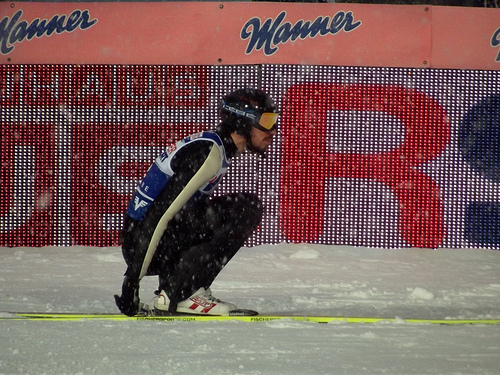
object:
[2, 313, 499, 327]
skis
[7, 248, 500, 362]
snow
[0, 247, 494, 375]
ground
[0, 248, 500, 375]
ice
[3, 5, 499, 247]
sign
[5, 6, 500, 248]
background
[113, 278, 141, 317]
gloves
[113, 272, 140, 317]
hands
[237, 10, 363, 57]
manner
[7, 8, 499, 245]
wall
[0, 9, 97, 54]
logos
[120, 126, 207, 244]
back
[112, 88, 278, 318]
man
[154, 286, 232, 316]
shoes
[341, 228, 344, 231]
led lights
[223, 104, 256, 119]
strap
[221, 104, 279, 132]
goggles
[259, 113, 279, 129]
tint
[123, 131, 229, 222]
vest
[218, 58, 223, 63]
rivets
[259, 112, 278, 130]
lens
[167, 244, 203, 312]
binder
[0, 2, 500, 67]
banner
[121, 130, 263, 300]
suit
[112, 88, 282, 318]
position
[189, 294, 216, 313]
accents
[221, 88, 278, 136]
helmet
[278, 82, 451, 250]
r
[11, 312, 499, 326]
object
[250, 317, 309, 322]
text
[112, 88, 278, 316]
athlete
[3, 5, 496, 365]
sport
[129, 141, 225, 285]
sleeve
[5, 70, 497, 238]
letters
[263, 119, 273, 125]
eyes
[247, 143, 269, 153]
chin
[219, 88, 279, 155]
head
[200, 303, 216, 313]
stripes